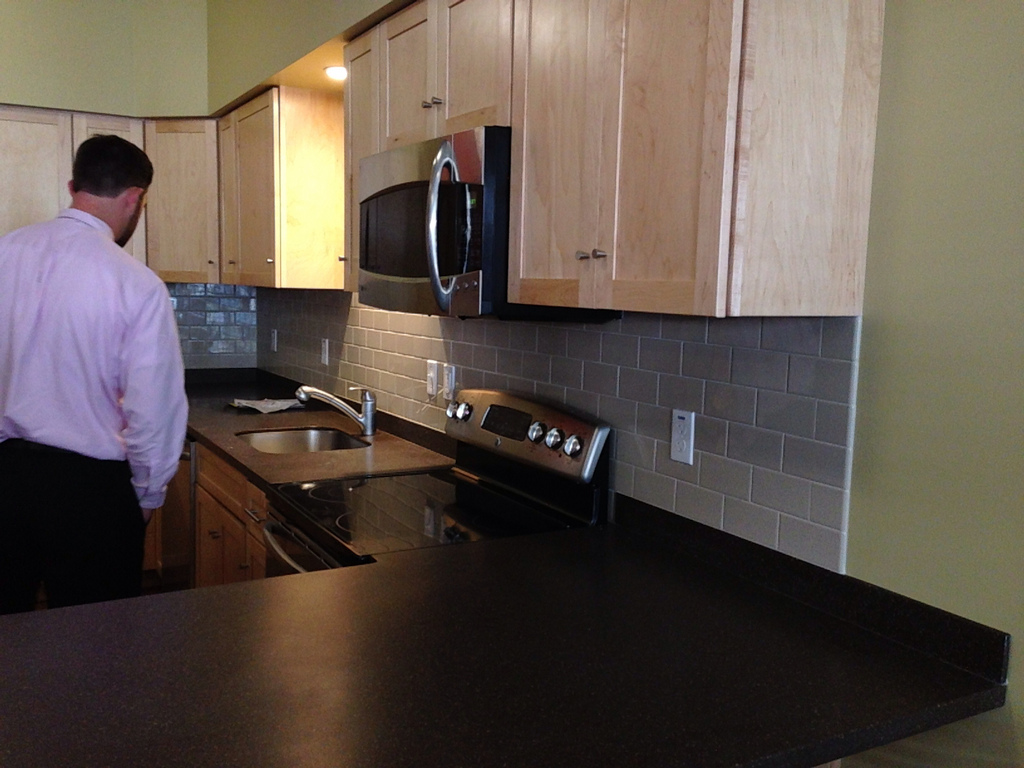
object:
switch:
[443, 363, 456, 400]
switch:
[425, 359, 436, 394]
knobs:
[528, 421, 548, 443]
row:
[444, 401, 472, 422]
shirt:
[0, 206, 192, 510]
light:
[325, 66, 349, 80]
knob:
[562, 432, 582, 457]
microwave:
[358, 125, 512, 319]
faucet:
[295, 386, 375, 437]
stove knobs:
[544, 427, 568, 449]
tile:
[810, 481, 848, 532]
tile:
[783, 432, 852, 490]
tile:
[814, 398, 855, 448]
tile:
[785, 356, 861, 407]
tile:
[821, 315, 864, 361]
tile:
[725, 494, 782, 550]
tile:
[536, 325, 568, 358]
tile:
[778, 513, 847, 576]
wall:
[205, 0, 1023, 768]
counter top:
[0, 367, 1016, 766]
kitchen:
[0, 0, 1024, 768]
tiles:
[731, 345, 789, 393]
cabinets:
[0, 0, 892, 319]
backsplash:
[255, 286, 858, 575]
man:
[0, 132, 192, 611]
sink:
[233, 427, 375, 457]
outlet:
[670, 409, 695, 466]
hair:
[69, 134, 152, 201]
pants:
[0, 437, 151, 614]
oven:
[266, 389, 616, 567]